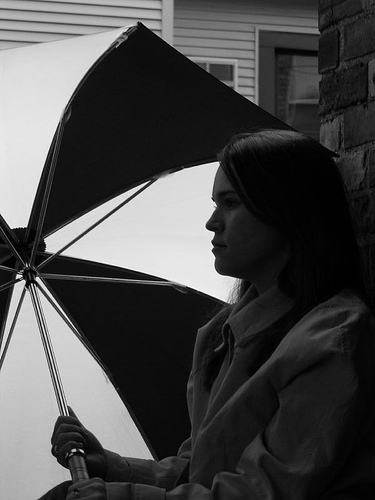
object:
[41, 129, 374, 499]
woman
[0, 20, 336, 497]
umbrella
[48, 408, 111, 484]
hand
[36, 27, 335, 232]
umbrella panels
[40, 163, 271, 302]
umbrella panels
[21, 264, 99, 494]
rods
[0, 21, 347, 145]
outwards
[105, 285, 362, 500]
raincoat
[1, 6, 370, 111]
house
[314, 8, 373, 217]
wall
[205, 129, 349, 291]
head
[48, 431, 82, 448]
finger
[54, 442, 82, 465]
finger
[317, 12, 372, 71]
bricks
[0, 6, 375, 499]
photo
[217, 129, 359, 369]
hair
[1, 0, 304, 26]
shingles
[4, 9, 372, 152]
backround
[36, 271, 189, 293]
spoke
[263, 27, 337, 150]
glass door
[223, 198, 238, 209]
eye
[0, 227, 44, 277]
piece